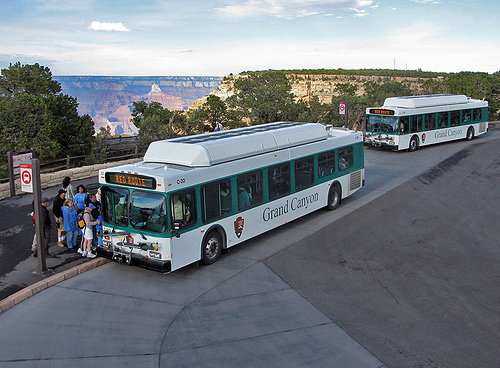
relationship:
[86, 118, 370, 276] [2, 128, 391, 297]
bus on street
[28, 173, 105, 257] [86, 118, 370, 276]
people getting on bus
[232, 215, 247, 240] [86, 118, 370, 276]
sign on bus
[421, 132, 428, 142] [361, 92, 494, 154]
sign on bus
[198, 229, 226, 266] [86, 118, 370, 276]
tire on bus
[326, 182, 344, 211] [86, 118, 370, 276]
tire on bus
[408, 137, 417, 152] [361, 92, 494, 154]
tire on bus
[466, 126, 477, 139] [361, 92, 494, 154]
tire on bus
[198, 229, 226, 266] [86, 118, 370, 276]
tire of bus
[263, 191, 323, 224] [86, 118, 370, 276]
grand canyon on bus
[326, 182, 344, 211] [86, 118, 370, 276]
tire of bus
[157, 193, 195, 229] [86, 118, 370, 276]
driver in bus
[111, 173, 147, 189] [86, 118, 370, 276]
red route on bus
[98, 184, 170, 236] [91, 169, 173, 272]
window if front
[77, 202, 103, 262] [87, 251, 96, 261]
girl wearing shoes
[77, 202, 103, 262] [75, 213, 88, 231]
girl wearing backpack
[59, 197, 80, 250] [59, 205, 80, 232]
woman wearing jacket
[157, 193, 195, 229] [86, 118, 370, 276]
driver of bus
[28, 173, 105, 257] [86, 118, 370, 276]
people boarding bus